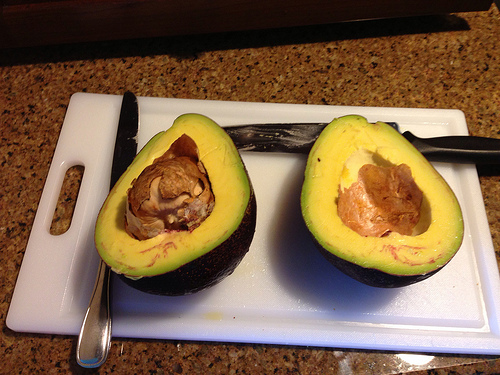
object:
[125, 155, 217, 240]
avocado pit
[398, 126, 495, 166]
knife handle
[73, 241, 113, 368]
knife handle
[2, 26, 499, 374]
granite countertop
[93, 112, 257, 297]
avocado half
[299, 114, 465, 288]
avocado half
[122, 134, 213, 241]
meat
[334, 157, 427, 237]
meat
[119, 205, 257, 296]
avocado skin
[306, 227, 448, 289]
avocado skin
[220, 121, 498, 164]
knife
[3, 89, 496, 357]
cutting board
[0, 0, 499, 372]
countertop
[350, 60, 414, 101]
ground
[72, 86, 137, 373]
knife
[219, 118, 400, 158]
knife blade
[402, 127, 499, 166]
handle